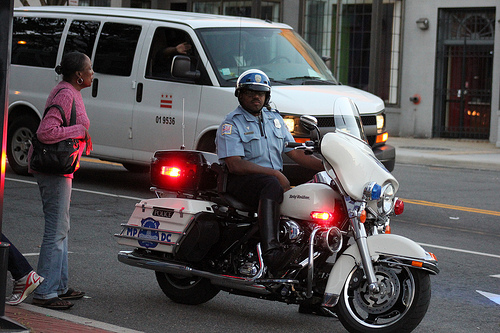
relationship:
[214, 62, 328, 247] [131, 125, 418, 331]
man on bike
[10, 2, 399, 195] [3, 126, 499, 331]
van on road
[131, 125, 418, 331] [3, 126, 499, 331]
bike on road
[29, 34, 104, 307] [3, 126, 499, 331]
woman on road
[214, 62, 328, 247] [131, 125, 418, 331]
man using bike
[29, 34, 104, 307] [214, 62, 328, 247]
woman beside man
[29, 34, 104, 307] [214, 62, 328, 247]
woman near man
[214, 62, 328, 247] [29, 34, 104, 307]
man near woman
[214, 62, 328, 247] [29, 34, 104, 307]
man next to woman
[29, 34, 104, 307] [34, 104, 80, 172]
woman with bag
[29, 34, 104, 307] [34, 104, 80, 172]
woman has bag